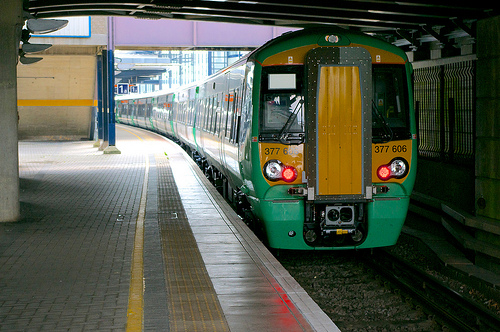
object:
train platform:
[0, 113, 310, 331]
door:
[315, 64, 367, 197]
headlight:
[262, 158, 299, 184]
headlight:
[375, 156, 410, 181]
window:
[370, 61, 412, 144]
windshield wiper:
[278, 95, 306, 142]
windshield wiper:
[372, 98, 399, 142]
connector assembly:
[301, 192, 367, 247]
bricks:
[123, 194, 131, 202]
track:
[374, 229, 497, 329]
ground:
[0, 139, 341, 332]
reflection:
[261, 278, 310, 329]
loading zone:
[0, 120, 148, 330]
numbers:
[374, 145, 381, 154]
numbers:
[275, 147, 281, 155]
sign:
[117, 84, 126, 95]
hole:
[473, 197, 489, 211]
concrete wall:
[472, 20, 498, 223]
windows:
[261, 63, 308, 144]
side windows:
[229, 88, 239, 144]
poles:
[94, 51, 105, 150]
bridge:
[0, 0, 500, 42]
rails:
[426, 270, 500, 322]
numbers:
[391, 144, 399, 153]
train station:
[0, 1, 492, 331]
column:
[0, 0, 22, 225]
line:
[112, 125, 160, 330]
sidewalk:
[3, 113, 340, 331]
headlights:
[281, 166, 299, 182]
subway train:
[114, 27, 427, 254]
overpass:
[99, 15, 310, 50]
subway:
[115, 24, 417, 255]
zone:
[8, 122, 334, 331]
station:
[3, 1, 498, 331]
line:
[16, 98, 98, 107]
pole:
[107, 49, 116, 149]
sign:
[20, 15, 93, 39]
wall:
[14, 16, 98, 142]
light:
[115, 31, 416, 250]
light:
[262, 157, 284, 183]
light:
[387, 156, 411, 180]